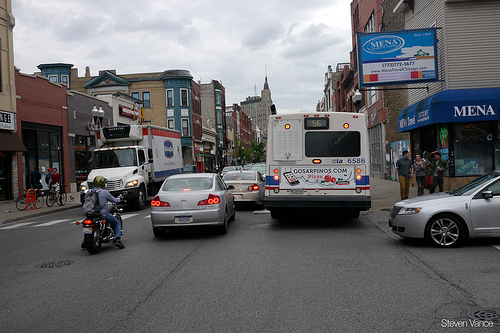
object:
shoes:
[112, 236, 127, 249]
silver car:
[150, 173, 236, 239]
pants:
[104, 209, 123, 242]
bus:
[260, 111, 372, 220]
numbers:
[346, 157, 354, 164]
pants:
[397, 175, 410, 199]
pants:
[103, 213, 122, 237]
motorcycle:
[74, 190, 130, 256]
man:
[80, 175, 127, 249]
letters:
[450, 104, 470, 120]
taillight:
[80, 218, 94, 226]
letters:
[340, 168, 348, 173]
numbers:
[309, 119, 316, 127]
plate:
[172, 215, 196, 225]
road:
[0, 176, 500, 333]